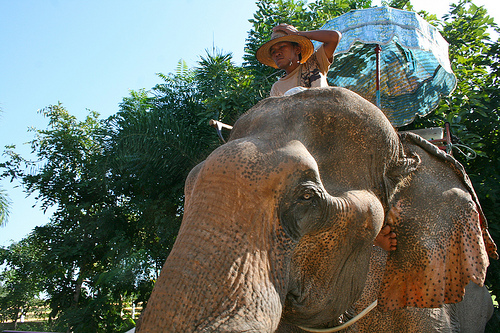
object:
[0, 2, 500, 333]
tree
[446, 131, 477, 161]
ground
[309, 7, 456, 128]
umbrella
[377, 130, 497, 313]
ear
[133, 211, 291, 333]
trunk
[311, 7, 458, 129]
blue umbrella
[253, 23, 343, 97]
man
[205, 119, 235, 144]
ax tool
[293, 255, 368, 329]
skin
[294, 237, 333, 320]
chin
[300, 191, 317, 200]
eye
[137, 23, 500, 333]
person/hat/elephant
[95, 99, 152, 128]
leaves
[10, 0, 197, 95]
blue sky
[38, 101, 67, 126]
tree leaves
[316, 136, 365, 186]
skin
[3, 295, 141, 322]
fence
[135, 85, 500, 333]
elephant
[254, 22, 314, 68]
hat